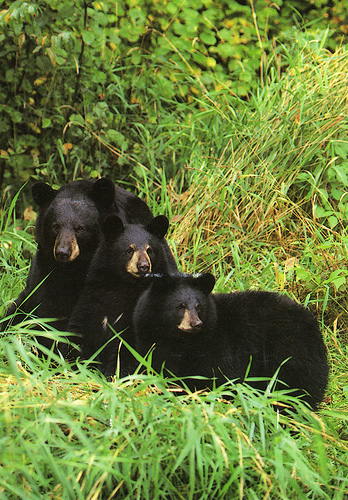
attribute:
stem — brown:
[65, 1, 87, 121]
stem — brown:
[15, 35, 30, 90]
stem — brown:
[123, 84, 130, 133]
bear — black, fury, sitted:
[75, 206, 184, 377]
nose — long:
[42, 238, 79, 266]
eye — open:
[48, 209, 92, 242]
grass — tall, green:
[45, 363, 208, 499]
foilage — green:
[183, 155, 346, 278]